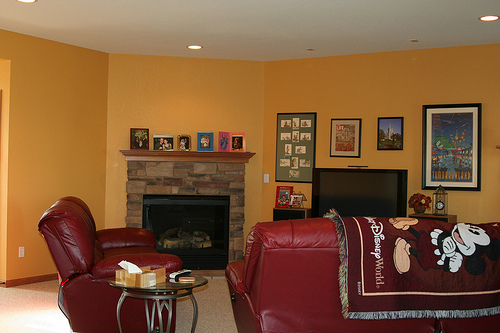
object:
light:
[188, 44, 208, 54]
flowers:
[406, 192, 431, 210]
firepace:
[117, 149, 257, 279]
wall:
[104, 50, 266, 247]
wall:
[264, 41, 498, 221]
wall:
[0, 28, 108, 287]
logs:
[157, 225, 213, 251]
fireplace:
[144, 195, 227, 262]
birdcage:
[432, 184, 449, 215]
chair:
[33, 195, 184, 333]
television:
[311, 165, 410, 220]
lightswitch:
[262, 171, 269, 184]